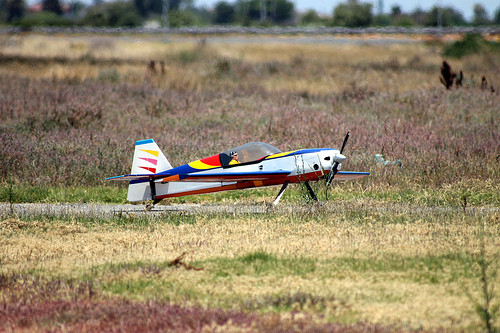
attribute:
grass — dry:
[286, 209, 436, 296]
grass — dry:
[2, 29, 496, 331]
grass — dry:
[5, 221, 495, 331]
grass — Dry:
[196, 222, 372, 251]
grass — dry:
[265, 38, 489, 170]